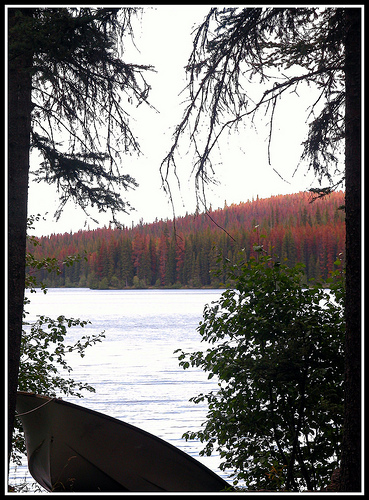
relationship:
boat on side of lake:
[13, 382, 243, 490] [25, 283, 352, 481]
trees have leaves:
[9, 7, 128, 483] [15, 17, 72, 51]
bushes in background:
[209, 244, 345, 492] [246, 420, 266, 421]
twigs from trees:
[252, 88, 304, 111] [9, 7, 128, 483]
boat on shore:
[13, 382, 243, 490] [11, 481, 363, 491]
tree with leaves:
[151, 231, 178, 283] [158, 243, 164, 248]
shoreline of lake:
[28, 280, 330, 287] [25, 283, 352, 481]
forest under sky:
[28, 195, 343, 286] [38, 5, 338, 202]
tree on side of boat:
[291, 11, 358, 498] [13, 382, 243, 490]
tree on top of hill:
[24, 189, 345, 290] [30, 189, 346, 287]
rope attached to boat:
[25, 392, 59, 419] [13, 382, 243, 490]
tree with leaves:
[291, 11, 358, 498] [15, 17, 72, 51]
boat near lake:
[13, 382, 243, 490] [25, 283, 352, 481]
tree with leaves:
[24, 189, 345, 290] [158, 243, 164, 248]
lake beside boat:
[25, 283, 352, 481] [13, 382, 243, 490]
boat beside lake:
[13, 382, 243, 490] [25, 283, 352, 481]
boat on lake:
[13, 382, 243, 490] [25, 283, 352, 481]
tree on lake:
[291, 11, 358, 498] [25, 283, 352, 481]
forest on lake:
[28, 195, 343, 286] [25, 283, 352, 481]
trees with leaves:
[9, 7, 128, 483] [15, 17, 72, 51]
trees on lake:
[9, 7, 128, 483] [25, 283, 352, 481]